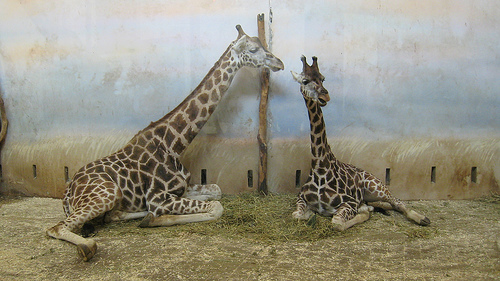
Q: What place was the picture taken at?
A: It was taken at the field.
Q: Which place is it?
A: It is a field.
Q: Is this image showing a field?
A: Yes, it is showing a field.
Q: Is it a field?
A: Yes, it is a field.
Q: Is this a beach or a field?
A: It is a field.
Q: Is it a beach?
A: No, it is a field.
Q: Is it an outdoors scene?
A: Yes, it is outdoors.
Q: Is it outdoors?
A: Yes, it is outdoors.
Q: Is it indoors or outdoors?
A: It is outdoors.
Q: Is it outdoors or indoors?
A: It is outdoors.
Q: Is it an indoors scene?
A: No, it is outdoors.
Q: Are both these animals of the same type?
A: Yes, all the animals are giraffes.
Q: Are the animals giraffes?
A: Yes, all the animals are giraffes.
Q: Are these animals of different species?
A: No, all the animals are giraffes.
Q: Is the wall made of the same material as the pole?
A: No, the wall is made of concrete and the pole is made of wood.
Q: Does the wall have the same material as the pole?
A: No, the wall is made of concrete and the pole is made of wood.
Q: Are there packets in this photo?
A: No, there are no packets.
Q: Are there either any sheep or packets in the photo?
A: No, there are no packets or sheep.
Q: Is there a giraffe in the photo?
A: Yes, there is a giraffe.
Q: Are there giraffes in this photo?
A: Yes, there is a giraffe.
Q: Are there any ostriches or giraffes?
A: Yes, there is a giraffe.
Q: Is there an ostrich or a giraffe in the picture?
A: Yes, there is a giraffe.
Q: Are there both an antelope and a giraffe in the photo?
A: No, there is a giraffe but no antelopes.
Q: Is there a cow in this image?
A: No, there are no cows.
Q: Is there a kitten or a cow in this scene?
A: No, there are no cows or kittens.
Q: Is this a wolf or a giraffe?
A: This is a giraffe.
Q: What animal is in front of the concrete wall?
A: The giraffe is in front of the wall.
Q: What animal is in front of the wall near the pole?
A: The animal is a giraffe.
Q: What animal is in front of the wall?
A: The animal is a giraffe.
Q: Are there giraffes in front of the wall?
A: Yes, there is a giraffe in front of the wall.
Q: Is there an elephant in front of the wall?
A: No, there is a giraffe in front of the wall.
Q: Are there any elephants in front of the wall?
A: No, there is a giraffe in front of the wall.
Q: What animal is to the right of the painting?
A: The animal is a giraffe.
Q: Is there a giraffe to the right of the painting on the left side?
A: Yes, there is a giraffe to the right of the painting.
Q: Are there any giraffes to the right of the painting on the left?
A: Yes, there is a giraffe to the right of the painting.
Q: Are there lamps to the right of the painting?
A: No, there is a giraffe to the right of the painting.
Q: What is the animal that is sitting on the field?
A: The animal is a giraffe.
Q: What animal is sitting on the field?
A: The animal is a giraffe.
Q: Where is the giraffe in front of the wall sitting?
A: The giraffe is sitting on the field.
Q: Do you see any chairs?
A: No, there are no chairs.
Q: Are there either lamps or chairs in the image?
A: No, there are no chairs or lamps.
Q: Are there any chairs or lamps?
A: No, there are no chairs or lamps.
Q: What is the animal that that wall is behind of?
A: The animal is a giraffe.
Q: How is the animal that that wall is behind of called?
A: The animal is a giraffe.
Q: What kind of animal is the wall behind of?
A: The wall is behind the giraffe.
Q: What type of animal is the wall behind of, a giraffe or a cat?
A: The wall is behind a giraffe.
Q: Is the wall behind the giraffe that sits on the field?
A: Yes, the wall is behind the giraffe.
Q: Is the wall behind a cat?
A: No, the wall is behind the giraffe.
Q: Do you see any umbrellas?
A: No, there are no umbrellas.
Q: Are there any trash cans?
A: No, there are no trash cans.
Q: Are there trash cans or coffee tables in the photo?
A: No, there are no trash cans or coffee tables.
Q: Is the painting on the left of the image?
A: Yes, the painting is on the left of the image.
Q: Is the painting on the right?
A: No, the painting is on the left of the image.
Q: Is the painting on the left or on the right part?
A: The painting is on the left of the image.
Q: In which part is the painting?
A: The painting is on the left of the image.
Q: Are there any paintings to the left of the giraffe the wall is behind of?
A: Yes, there is a painting to the left of the giraffe.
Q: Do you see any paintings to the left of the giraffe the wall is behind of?
A: Yes, there is a painting to the left of the giraffe.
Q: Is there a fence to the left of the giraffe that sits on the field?
A: No, there is a painting to the left of the giraffe.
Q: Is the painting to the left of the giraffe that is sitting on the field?
A: Yes, the painting is to the left of the giraffe.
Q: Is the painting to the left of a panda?
A: No, the painting is to the left of the giraffe.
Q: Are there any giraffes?
A: Yes, there is a giraffe.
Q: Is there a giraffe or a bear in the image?
A: Yes, there is a giraffe.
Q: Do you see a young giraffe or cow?
A: Yes, there is a young giraffe.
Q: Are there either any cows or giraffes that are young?
A: Yes, the giraffe is young.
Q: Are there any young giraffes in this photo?
A: Yes, there is a young giraffe.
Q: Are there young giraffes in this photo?
A: Yes, there is a young giraffe.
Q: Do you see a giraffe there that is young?
A: Yes, there is a giraffe that is young.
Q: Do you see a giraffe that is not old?
A: Yes, there is an young giraffe.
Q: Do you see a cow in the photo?
A: No, there are no cows.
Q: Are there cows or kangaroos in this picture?
A: No, there are no cows or kangaroos.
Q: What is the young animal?
A: The animal is a giraffe.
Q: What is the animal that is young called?
A: The animal is a giraffe.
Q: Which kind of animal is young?
A: The animal is a giraffe.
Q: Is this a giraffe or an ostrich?
A: This is a giraffe.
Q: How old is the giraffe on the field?
A: The giraffe is young.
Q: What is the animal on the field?
A: The animal is a giraffe.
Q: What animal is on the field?
A: The animal is a giraffe.